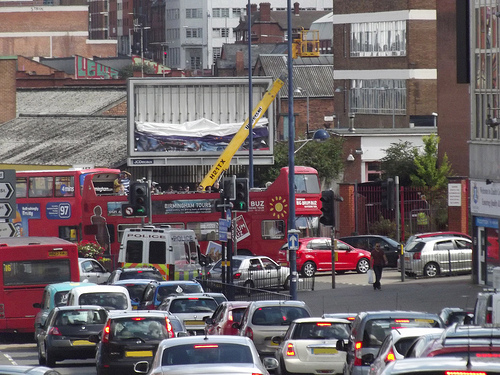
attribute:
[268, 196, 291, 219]
sun — yellow, logo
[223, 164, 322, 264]
bus — double-decker, red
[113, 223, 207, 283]
van — white, police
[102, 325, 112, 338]
light — red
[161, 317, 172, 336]
light — red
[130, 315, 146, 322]
light — red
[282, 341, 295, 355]
light — red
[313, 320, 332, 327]
light — red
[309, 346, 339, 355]
plate — yellow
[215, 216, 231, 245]
sign — blue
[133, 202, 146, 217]
light — green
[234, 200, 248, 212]
light — green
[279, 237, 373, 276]
car — red, compact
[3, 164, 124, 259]
bus — double-decker, red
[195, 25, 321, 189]
crane — yellow, large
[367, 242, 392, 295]
person — walking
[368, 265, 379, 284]
bag — white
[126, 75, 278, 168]
billboard — changed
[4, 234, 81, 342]
bus — red, small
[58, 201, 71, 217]
number — 97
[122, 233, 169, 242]
word — police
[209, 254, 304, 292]
car — silver, small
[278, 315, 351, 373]
car — white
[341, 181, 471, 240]
fence — metal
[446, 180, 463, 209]
sign — black, white